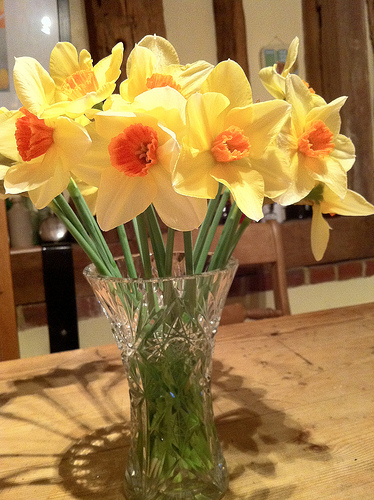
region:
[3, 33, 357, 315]
Flowers in a vase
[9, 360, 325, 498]
Shadows reflecting on the table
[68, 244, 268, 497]
The vase is see-through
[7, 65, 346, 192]
the inside of these flowers are orange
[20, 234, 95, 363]
black wood on the chair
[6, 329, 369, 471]
The table has signs on wear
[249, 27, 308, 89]
An item on the wall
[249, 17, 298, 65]
The item is being hung by a nail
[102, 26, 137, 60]
Hole in the wood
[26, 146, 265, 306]
The stems are green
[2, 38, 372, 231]
bouquet of jonquils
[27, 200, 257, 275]
green stems on jonquils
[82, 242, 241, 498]
clear cut glass vase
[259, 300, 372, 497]
unfinished wooden table top.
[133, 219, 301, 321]
top of a chair back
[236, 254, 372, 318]
low wall trimmed in red brick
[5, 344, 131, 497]
a shadow cast from a glass vase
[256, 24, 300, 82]
small picture hanging on the wall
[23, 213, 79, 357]
a black belt with silver buckle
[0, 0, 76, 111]
wall hanging with a silver frame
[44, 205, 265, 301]
fifteen green flower stalks in clear glass vase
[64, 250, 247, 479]
clear glass vase with flowers in it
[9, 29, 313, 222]
bouqet of yellow and orange flowers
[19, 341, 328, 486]
shadow of bouquet of flowers invase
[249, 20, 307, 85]
small peice of kitchen art hanging on wall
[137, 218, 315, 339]
wooden chair behind flowers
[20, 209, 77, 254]
metallic object on counter behind flowers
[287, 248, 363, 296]
red brick and mortar trim along counter in room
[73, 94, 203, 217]
brightly colored yellow flower with an orange middle area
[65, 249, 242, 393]
scratchy design on clear glass flower vase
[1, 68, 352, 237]
a bouquet of yellow flowers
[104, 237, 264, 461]
a glass flower vase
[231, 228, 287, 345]
a wooden chair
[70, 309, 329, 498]
a wooden table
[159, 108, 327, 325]
yellow flowers with green stems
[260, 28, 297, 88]
a plaque hanging on the wall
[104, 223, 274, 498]
a clear glass vase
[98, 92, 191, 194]
a yellow flower with orange middle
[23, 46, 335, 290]
several yellow flowers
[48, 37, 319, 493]
several yellow flowers in a glass vase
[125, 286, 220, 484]
a glass vase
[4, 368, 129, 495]
a shadow on the table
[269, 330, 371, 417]
the table is brown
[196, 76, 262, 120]
the flowers are yellow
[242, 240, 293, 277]
a chair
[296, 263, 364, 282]
bricks on the wall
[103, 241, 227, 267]
the stems are green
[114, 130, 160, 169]
orange flowers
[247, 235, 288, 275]
the chair is brown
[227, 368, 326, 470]
there is a shadow on the table